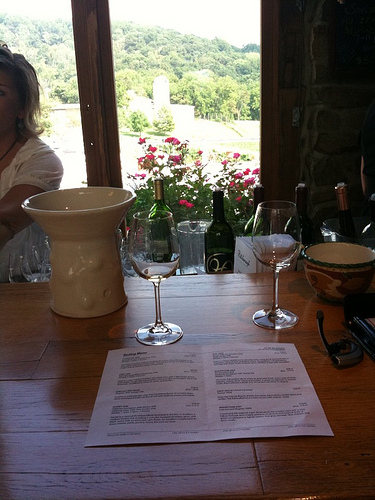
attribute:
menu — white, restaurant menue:
[100, 325, 329, 469]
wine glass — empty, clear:
[238, 203, 309, 321]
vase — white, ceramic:
[38, 179, 131, 314]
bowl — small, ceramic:
[301, 237, 367, 300]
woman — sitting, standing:
[8, 58, 73, 219]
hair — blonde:
[14, 68, 57, 133]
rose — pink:
[159, 130, 193, 164]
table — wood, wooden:
[18, 341, 100, 454]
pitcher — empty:
[176, 212, 214, 270]